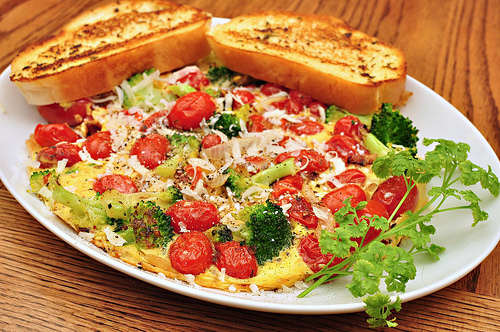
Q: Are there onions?
A: Yes, there is an onion.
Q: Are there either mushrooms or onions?
A: Yes, there is an onion.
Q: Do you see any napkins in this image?
A: No, there are no napkins.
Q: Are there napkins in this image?
A: No, there are no napkins.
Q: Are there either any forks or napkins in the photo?
A: No, there are no napkins or forks.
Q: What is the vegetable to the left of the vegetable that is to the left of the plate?
A: The vegetable is an onion.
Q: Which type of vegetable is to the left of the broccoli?
A: The vegetable is an onion.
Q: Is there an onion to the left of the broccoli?
A: Yes, there is an onion to the left of the broccoli.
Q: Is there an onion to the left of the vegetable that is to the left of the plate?
A: Yes, there is an onion to the left of the broccoli.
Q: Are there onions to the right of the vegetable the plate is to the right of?
A: No, the onion is to the left of the broccoli.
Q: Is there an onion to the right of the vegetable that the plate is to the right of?
A: No, the onion is to the left of the broccoli.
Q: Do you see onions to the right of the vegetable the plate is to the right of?
A: No, the onion is to the left of the broccoli.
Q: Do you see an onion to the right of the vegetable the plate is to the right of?
A: No, the onion is to the left of the broccoli.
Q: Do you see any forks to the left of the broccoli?
A: No, there is an onion to the left of the broccoli.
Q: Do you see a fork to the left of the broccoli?
A: No, there is an onion to the left of the broccoli.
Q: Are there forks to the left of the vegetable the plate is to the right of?
A: No, there is an onion to the left of the broccoli.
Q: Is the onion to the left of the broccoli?
A: Yes, the onion is to the left of the broccoli.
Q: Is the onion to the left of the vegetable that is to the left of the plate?
A: Yes, the onion is to the left of the broccoli.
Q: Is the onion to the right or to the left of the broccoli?
A: The onion is to the left of the broccoli.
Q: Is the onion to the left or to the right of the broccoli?
A: The onion is to the left of the broccoli.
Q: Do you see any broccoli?
A: Yes, there is broccoli.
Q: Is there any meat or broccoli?
A: Yes, there is broccoli.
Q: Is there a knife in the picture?
A: No, there are no knives.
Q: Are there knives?
A: No, there are no knives.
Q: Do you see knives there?
A: No, there are no knives.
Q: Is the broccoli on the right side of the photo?
A: Yes, the broccoli is on the right of the image.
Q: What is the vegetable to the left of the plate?
A: The vegetable is broccoli.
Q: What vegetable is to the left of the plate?
A: The vegetable is broccoli.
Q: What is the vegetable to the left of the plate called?
A: The vegetable is broccoli.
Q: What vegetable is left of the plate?
A: The vegetable is broccoli.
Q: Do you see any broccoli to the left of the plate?
A: Yes, there is broccoli to the left of the plate.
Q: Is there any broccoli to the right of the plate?
A: No, the broccoli is to the left of the plate.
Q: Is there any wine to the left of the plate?
A: No, there is broccoli to the left of the plate.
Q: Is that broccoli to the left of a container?
A: No, the broccoli is to the left of a plate.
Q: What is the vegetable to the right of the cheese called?
A: The vegetable is broccoli.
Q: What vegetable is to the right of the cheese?
A: The vegetable is broccoli.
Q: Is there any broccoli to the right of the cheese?
A: Yes, there is broccoli to the right of the cheese.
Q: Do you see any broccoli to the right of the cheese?
A: Yes, there is broccoli to the right of the cheese.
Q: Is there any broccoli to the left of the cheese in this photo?
A: No, the broccoli is to the right of the cheese.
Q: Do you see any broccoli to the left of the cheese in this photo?
A: No, the broccoli is to the right of the cheese.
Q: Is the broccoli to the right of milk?
A: No, the broccoli is to the right of the cheese.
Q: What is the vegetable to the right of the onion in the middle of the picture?
A: The vegetable is broccoli.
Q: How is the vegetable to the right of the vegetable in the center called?
A: The vegetable is broccoli.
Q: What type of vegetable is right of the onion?
A: The vegetable is broccoli.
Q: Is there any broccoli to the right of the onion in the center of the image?
A: Yes, there is broccoli to the right of the onion.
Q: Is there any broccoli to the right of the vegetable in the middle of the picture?
A: Yes, there is broccoli to the right of the onion.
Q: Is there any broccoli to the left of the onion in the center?
A: No, the broccoli is to the right of the onion.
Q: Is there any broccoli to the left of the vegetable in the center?
A: No, the broccoli is to the right of the onion.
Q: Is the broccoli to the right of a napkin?
A: No, the broccoli is to the right of the onion.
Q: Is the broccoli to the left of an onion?
A: No, the broccoli is to the right of an onion.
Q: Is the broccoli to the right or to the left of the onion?
A: The broccoli is to the right of the onion.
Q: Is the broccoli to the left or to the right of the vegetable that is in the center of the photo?
A: The broccoli is to the right of the onion.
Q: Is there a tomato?
A: Yes, there is a tomato.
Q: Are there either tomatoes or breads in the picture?
A: Yes, there is a tomato.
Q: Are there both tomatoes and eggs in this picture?
A: Yes, there are both a tomato and an egg.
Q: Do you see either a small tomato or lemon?
A: Yes, there is a small tomato.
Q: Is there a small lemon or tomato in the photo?
A: Yes, there is a small tomato.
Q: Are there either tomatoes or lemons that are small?
A: Yes, the tomato is small.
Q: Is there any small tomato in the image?
A: Yes, there is a small tomato.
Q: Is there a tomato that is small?
A: Yes, there is a tomato that is small.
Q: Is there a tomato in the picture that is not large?
A: Yes, there is a small tomato.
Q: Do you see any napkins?
A: No, there are no napkins.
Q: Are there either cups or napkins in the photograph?
A: No, there are no napkins or cups.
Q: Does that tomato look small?
A: Yes, the tomato is small.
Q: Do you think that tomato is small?
A: Yes, the tomato is small.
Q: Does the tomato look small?
A: Yes, the tomato is small.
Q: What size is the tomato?
A: The tomato is small.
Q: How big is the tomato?
A: The tomato is small.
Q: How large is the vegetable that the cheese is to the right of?
A: The tomato is small.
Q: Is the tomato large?
A: No, the tomato is small.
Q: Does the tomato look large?
A: No, the tomato is small.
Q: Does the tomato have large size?
A: No, the tomato is small.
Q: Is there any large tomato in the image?
A: No, there is a tomato but it is small.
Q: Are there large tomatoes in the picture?
A: No, there is a tomato but it is small.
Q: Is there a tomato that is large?
A: No, there is a tomato but it is small.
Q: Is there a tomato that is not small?
A: No, there is a tomato but it is small.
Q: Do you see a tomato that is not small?
A: No, there is a tomato but it is small.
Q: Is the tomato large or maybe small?
A: The tomato is small.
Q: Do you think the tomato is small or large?
A: The tomato is small.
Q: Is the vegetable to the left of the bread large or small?
A: The tomato is small.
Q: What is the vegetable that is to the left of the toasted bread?
A: The vegetable is a tomato.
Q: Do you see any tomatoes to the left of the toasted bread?
A: Yes, there is a tomato to the left of the bread.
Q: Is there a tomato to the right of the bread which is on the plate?
A: No, the tomato is to the left of the bread.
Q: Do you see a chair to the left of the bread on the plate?
A: No, there is a tomato to the left of the bread.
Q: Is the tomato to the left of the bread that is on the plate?
A: Yes, the tomato is to the left of the bread.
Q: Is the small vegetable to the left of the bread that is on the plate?
A: Yes, the tomato is to the left of the bread.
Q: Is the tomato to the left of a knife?
A: No, the tomato is to the left of the bread.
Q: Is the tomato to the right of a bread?
A: No, the tomato is to the left of a bread.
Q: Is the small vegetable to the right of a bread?
A: No, the tomato is to the left of a bread.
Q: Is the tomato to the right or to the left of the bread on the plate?
A: The tomato is to the left of the bread.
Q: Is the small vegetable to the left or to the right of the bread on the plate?
A: The tomato is to the left of the bread.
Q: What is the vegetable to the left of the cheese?
A: The vegetable is a tomato.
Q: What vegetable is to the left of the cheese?
A: The vegetable is a tomato.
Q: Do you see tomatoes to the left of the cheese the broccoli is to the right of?
A: Yes, there is a tomato to the left of the cheese.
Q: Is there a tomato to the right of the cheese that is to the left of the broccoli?
A: No, the tomato is to the left of the cheese.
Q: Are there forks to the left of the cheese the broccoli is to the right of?
A: No, there is a tomato to the left of the cheese.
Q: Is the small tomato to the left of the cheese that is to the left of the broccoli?
A: Yes, the tomato is to the left of the cheese.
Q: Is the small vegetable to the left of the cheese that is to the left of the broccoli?
A: Yes, the tomato is to the left of the cheese.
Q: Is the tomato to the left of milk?
A: No, the tomato is to the left of the cheese.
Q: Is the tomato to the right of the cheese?
A: No, the tomato is to the left of the cheese.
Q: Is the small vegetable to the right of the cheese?
A: No, the tomato is to the left of the cheese.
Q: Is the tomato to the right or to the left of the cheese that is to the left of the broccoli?
A: The tomato is to the left of the cheese.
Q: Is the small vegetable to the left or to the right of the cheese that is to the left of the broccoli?
A: The tomato is to the left of the cheese.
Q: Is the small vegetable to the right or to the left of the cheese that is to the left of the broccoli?
A: The tomato is to the left of the cheese.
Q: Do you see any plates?
A: Yes, there is a plate.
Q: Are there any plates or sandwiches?
A: Yes, there is a plate.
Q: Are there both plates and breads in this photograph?
A: Yes, there are both a plate and a bread.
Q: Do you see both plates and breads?
A: Yes, there are both a plate and a bread.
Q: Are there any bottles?
A: No, there are no bottles.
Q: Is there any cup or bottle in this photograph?
A: No, there are no bottles or cups.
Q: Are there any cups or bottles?
A: No, there are no bottles or cups.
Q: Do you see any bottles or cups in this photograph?
A: No, there are no bottles or cups.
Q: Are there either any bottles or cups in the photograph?
A: No, there are no bottles or cups.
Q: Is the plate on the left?
A: No, the plate is on the right of the image.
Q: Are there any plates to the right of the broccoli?
A: Yes, there is a plate to the right of the broccoli.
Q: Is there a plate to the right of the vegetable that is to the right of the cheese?
A: Yes, there is a plate to the right of the broccoli.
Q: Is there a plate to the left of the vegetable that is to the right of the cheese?
A: No, the plate is to the right of the broccoli.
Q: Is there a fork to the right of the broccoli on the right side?
A: No, there is a plate to the right of the broccoli.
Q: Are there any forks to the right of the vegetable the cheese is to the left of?
A: No, there is a plate to the right of the broccoli.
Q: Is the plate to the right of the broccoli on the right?
A: Yes, the plate is to the right of the broccoli.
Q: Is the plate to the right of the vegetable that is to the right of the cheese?
A: Yes, the plate is to the right of the broccoli.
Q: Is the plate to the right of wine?
A: No, the plate is to the right of the broccoli.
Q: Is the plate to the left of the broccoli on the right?
A: No, the plate is to the right of the broccoli.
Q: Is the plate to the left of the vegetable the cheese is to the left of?
A: No, the plate is to the right of the broccoli.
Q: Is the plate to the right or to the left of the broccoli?
A: The plate is to the right of the broccoli.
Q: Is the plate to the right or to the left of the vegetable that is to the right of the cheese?
A: The plate is to the right of the broccoli.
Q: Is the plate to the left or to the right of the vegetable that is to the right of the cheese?
A: The plate is to the right of the broccoli.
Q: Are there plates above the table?
A: Yes, there is a plate above the table.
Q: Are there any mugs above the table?
A: No, there is a plate above the table.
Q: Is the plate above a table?
A: Yes, the plate is above a table.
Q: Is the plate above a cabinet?
A: No, the plate is above a table.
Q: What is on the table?
A: The plate is on the table.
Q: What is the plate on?
A: The plate is on the table.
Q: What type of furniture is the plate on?
A: The plate is on the table.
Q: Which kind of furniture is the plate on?
A: The plate is on the table.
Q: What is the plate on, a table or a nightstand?
A: The plate is on a table.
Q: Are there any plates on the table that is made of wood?
A: Yes, there is a plate on the table.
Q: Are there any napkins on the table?
A: No, there is a plate on the table.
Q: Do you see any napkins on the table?
A: No, there is a plate on the table.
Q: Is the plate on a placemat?
A: No, the plate is on the table.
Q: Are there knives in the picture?
A: No, there are no knives.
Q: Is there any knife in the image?
A: No, there are no knives.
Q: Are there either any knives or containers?
A: No, there are no knives or containers.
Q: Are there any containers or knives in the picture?
A: No, there are no knives or containers.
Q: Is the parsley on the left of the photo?
A: No, the parsley is on the right of the image.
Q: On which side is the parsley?
A: The parsley is on the right of the image.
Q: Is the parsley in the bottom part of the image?
A: Yes, the parsley is in the bottom of the image.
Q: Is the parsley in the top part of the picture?
A: No, the parsley is in the bottom of the image.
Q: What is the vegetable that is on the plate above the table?
A: The vegetable is parsley.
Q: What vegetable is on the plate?
A: The vegetable is parsley.